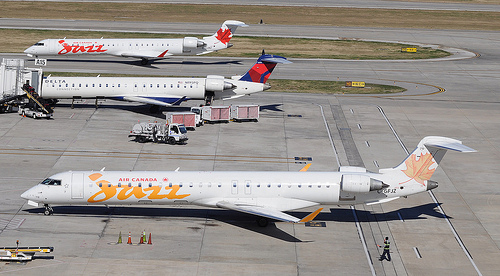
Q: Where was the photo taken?
A: It was taken at the airport.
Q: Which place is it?
A: It is an airport.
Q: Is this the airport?
A: Yes, it is the airport.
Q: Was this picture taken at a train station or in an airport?
A: It was taken at an airport.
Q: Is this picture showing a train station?
A: No, the picture is showing an airport.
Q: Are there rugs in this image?
A: No, there are no rugs.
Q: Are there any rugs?
A: No, there are no rugs.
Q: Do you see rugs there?
A: No, there are no rugs.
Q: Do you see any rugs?
A: No, there are no rugs.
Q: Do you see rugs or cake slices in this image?
A: No, there are no rugs or cake slices.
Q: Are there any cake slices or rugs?
A: No, there are no rugs or cake slices.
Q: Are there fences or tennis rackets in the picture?
A: No, there are no fences or tennis rackets.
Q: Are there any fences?
A: No, there are no fences.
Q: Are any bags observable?
A: No, there are no bags.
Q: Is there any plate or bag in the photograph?
A: No, there are no bags or plates.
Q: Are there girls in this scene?
A: No, there are no girls.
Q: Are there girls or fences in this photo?
A: No, there are no girls or fences.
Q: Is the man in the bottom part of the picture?
A: Yes, the man is in the bottom of the image.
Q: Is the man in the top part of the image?
A: No, the man is in the bottom of the image.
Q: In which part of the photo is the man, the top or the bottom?
A: The man is in the bottom of the image.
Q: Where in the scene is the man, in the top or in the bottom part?
A: The man is in the bottom of the image.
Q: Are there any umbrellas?
A: No, there are no umbrellas.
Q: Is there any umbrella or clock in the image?
A: No, there are no umbrellas or clocks.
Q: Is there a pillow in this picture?
A: No, there are no pillows.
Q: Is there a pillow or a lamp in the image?
A: No, there are no pillows or lamps.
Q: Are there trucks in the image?
A: Yes, there is a truck.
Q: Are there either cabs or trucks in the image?
A: Yes, there is a truck.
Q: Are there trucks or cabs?
A: Yes, there is a truck.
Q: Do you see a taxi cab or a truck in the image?
A: Yes, there is a truck.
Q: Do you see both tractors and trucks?
A: No, there is a truck but no tractors.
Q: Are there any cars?
A: No, there are no cars.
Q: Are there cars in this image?
A: No, there are no cars.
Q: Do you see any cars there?
A: No, there are no cars.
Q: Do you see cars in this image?
A: No, there are no cars.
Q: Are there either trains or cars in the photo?
A: No, there are no cars or trains.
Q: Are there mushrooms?
A: No, there are no mushrooms.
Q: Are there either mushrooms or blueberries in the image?
A: No, there are no mushrooms or blueberries.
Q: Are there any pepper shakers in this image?
A: No, there are no pepper shakers.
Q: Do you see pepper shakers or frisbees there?
A: No, there are no pepper shakers or frisbees.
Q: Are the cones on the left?
A: Yes, the cones are on the left of the image.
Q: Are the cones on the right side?
A: No, the cones are on the left of the image.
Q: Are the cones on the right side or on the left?
A: The cones are on the left of the image.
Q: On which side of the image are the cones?
A: The cones are on the left of the image.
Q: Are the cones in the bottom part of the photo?
A: Yes, the cones are in the bottom of the image.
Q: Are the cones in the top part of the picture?
A: No, the cones are in the bottom of the image.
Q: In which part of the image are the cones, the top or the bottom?
A: The cones are in the bottom of the image.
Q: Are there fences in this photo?
A: No, there are no fences.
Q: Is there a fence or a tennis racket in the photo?
A: No, there are no fences or rackets.